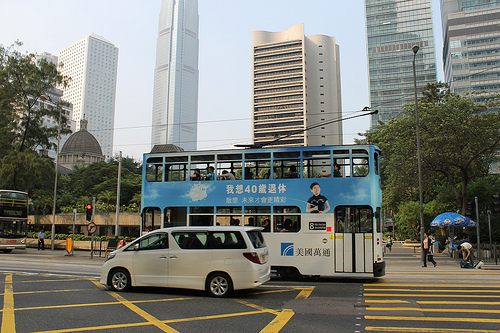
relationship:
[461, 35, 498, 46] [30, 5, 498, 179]
windows on building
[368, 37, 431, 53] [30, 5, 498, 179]
windows on building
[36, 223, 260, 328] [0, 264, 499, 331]
cars on road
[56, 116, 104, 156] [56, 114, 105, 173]
dome on building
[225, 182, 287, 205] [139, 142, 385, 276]
chinese writing on side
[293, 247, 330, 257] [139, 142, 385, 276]
chinese writing on side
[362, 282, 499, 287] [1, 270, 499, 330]
stripe on street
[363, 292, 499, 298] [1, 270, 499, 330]
stripe on street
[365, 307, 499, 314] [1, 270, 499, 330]
stripe on street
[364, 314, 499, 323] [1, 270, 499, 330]
stripe on street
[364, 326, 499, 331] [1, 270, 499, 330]
stripe on street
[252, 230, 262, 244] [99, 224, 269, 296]
window on van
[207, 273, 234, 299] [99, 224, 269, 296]
wheel on van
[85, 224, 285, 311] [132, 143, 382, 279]
van next to bus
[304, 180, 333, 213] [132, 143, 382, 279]
man on bus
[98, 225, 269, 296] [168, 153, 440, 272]
car by bus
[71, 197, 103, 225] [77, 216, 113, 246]
stop light on sign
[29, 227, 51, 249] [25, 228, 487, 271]
man on sidewalk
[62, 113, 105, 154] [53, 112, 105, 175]
roof behind building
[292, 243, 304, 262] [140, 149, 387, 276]
chinese on bus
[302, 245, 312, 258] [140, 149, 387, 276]
chinese on bus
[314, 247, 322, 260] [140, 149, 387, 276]
chinese on bus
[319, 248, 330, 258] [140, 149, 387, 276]
chinese on bus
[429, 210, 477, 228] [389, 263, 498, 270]
umberella on sidewalk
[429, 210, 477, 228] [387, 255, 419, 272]
umberella on sidewalk